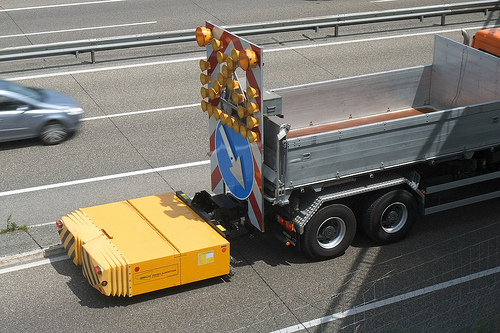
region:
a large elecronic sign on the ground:
[42, 180, 241, 302]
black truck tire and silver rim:
[305, 201, 365, 261]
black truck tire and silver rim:
[360, 187, 423, 246]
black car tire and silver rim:
[35, 118, 68, 149]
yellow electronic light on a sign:
[244, 126, 263, 147]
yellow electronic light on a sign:
[236, 120, 250, 139]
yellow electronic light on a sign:
[242, 100, 262, 115]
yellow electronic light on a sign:
[241, 85, 259, 102]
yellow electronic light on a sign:
[217, 109, 230, 126]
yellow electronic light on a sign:
[191, 23, 213, 48]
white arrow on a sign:
[214, 127, 254, 189]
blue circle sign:
[193, 108, 262, 202]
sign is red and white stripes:
[195, 119, 281, 227]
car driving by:
[0, 64, 90, 145]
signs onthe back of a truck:
[210, 129, 278, 222]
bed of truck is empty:
[279, 71, 498, 152]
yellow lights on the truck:
[194, 25, 272, 135]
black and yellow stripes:
[49, 224, 115, 301]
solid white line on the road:
[14, 150, 222, 197]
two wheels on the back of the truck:
[309, 201, 429, 254]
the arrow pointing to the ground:
[211, 116, 256, 202]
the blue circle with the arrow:
[211, 120, 261, 205]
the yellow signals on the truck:
[192, 23, 262, 145]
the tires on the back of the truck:
[306, 189, 415, 257]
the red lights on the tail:
[274, 212, 303, 257]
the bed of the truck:
[266, 35, 498, 158]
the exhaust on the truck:
[459, 23, 471, 48]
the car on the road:
[0, 77, 94, 141]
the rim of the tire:
[40, 115, 67, 148]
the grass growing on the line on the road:
[0, 212, 33, 242]